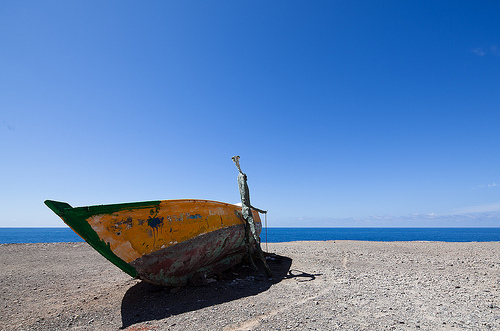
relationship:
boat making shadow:
[44, 156, 263, 294] [118, 250, 324, 330]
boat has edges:
[44, 156, 263, 294] [44, 199, 263, 289]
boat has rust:
[44, 156, 263, 294] [128, 221, 263, 284]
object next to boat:
[230, 155, 277, 281] [44, 156, 263, 294]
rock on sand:
[315, 298, 321, 306] [0, 239, 499, 331]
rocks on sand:
[1, 240, 500, 331] [0, 239, 499, 331]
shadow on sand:
[118, 250, 323, 330] [0, 239, 499, 331]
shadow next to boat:
[118, 250, 324, 330] [44, 156, 263, 294]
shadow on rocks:
[118, 250, 324, 330] [1, 240, 500, 331]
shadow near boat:
[118, 250, 324, 330] [44, 156, 263, 294]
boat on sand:
[44, 156, 263, 294] [0, 239, 499, 331]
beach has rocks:
[0, 239, 499, 331] [1, 240, 500, 331]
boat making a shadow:
[44, 156, 263, 294] [118, 250, 324, 330]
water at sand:
[1, 227, 499, 243] [0, 239, 499, 331]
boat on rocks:
[44, 156, 263, 294] [1, 240, 500, 331]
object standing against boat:
[230, 155, 277, 281] [44, 156, 263, 294]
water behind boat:
[1, 227, 499, 243] [44, 156, 263, 294]